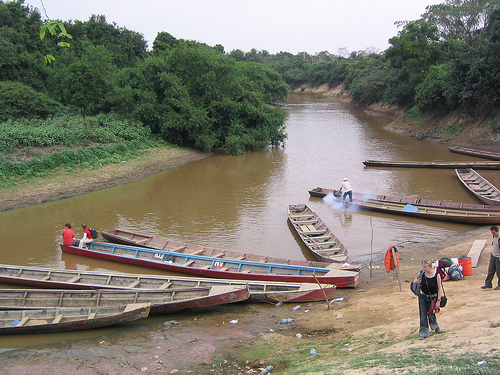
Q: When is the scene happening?
A: During the day.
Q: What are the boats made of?
A: Wood.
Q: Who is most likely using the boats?
A: Fishermen.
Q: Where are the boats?
A: River.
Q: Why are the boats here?
A: Use on water.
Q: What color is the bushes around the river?
A: Green.